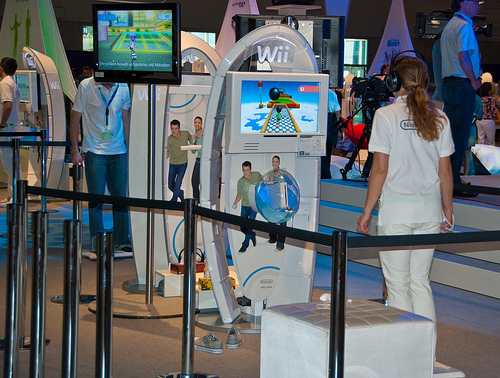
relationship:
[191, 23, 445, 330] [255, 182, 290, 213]
station for wii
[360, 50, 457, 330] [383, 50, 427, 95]
woman with headphones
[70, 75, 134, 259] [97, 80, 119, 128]
guy uses a lanyard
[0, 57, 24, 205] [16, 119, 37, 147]
man by console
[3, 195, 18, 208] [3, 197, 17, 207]
pair of shoes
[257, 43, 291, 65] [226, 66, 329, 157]
logo above tv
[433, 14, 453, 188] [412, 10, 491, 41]
man holds camera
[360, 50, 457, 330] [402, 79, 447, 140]
woman with pony tail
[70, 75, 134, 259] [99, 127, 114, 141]
man with badge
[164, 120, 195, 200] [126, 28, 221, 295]
man pictured on a sign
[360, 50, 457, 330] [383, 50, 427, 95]
woman has headphones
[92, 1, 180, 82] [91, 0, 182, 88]
tv has a monitor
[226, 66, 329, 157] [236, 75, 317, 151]
game on monitor